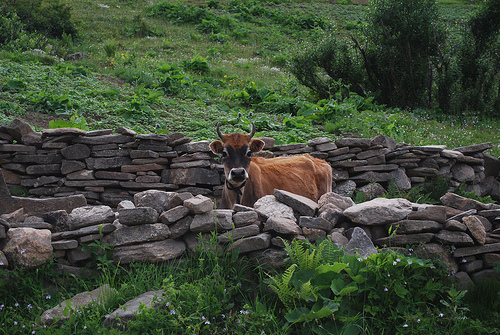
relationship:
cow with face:
[209, 123, 332, 207] [209, 135, 264, 186]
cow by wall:
[209, 123, 332, 207] [0, 125, 221, 192]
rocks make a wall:
[61, 145, 90, 160] [0, 125, 221, 192]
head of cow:
[206, 120, 265, 188] [209, 123, 332, 207]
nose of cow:
[230, 168, 245, 182] [209, 123, 332, 207]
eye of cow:
[247, 152, 253, 159] [209, 123, 332, 207]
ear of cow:
[251, 140, 266, 153] [209, 123, 332, 207]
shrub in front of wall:
[282, 240, 454, 328] [1, 190, 500, 296]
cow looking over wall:
[209, 123, 332, 207] [1, 190, 500, 296]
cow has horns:
[209, 123, 332, 207] [247, 122, 255, 135]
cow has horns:
[209, 123, 332, 207] [215, 121, 222, 138]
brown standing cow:
[268, 162, 303, 179] [209, 123, 332, 207]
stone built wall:
[387, 223, 440, 233] [1, 190, 500, 296]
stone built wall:
[441, 192, 485, 212] [1, 190, 500, 296]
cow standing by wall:
[209, 123, 332, 207] [0, 125, 221, 192]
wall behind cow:
[0, 125, 221, 192] [209, 123, 332, 207]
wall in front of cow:
[1, 190, 500, 296] [209, 123, 332, 207]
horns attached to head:
[247, 122, 255, 135] [206, 120, 265, 188]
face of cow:
[209, 135, 264, 186] [209, 123, 332, 207]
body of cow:
[249, 154, 332, 202] [209, 123, 332, 207]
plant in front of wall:
[92, 229, 114, 281] [1, 190, 500, 296]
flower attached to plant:
[383, 286, 389, 294] [366, 251, 445, 320]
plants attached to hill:
[237, 77, 382, 123] [72, 0, 361, 91]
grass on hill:
[251, 11, 316, 43] [72, 0, 361, 91]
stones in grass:
[39, 287, 168, 332] [2, 269, 199, 334]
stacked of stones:
[111, 193, 216, 265] [115, 188, 188, 223]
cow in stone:
[209, 123, 332, 207] [4, 124, 499, 278]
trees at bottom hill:
[335, 2, 499, 119] [72, 0, 361, 91]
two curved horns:
[216, 121, 256, 136] [247, 122, 255, 135]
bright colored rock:
[262, 201, 278, 214] [255, 195, 296, 223]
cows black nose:
[209, 123, 332, 207] [230, 168, 245, 182]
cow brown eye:
[209, 123, 332, 207] [247, 152, 253, 159]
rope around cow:
[225, 181, 248, 195] [209, 123, 332, 207]